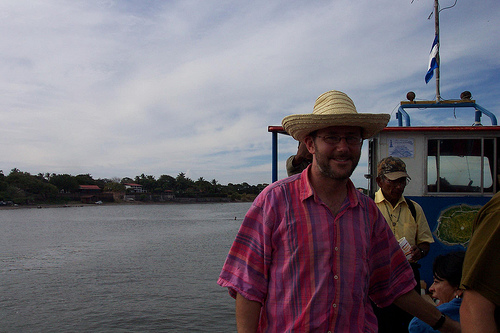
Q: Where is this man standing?
A: On a boat.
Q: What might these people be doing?
A: Taking a tour.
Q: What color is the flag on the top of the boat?
A: White and blue.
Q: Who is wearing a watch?
A: The man with the straw hat.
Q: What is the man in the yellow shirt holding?
A: Paper.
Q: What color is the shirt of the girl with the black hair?
A: Blue.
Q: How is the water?
A: Calm.